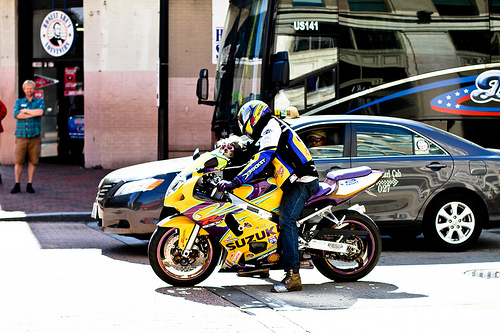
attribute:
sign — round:
[26, 11, 100, 66]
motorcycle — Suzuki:
[143, 124, 441, 307]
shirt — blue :
[12, 92, 51, 139]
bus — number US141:
[184, 6, 492, 163]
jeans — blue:
[273, 171, 321, 268]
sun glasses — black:
[308, 135, 324, 142]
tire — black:
[422, 186, 484, 248]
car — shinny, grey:
[310, 111, 497, 246]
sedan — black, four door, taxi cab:
[87, 115, 498, 245]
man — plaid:
[9, 79, 44, 193]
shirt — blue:
[13, 95, 44, 136]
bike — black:
[142, 135, 396, 298]